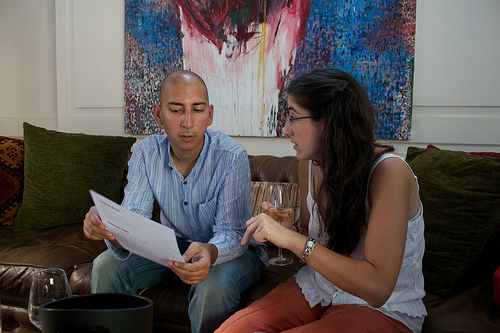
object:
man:
[82, 67, 272, 332]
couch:
[0, 118, 499, 331]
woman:
[214, 68, 434, 333]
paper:
[88, 188, 187, 271]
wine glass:
[266, 183, 295, 267]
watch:
[298, 235, 319, 267]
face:
[306, 240, 315, 249]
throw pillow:
[9, 121, 137, 237]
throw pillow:
[400, 144, 500, 299]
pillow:
[0, 134, 26, 229]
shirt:
[103, 127, 272, 268]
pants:
[213, 272, 415, 332]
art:
[120, 0, 419, 140]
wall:
[1, 0, 500, 160]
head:
[152, 70, 214, 151]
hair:
[283, 66, 397, 257]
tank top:
[294, 151, 432, 333]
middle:
[178, 0, 311, 138]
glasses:
[285, 111, 313, 124]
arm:
[241, 157, 413, 309]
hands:
[165, 240, 213, 286]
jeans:
[91, 234, 265, 333]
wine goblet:
[28, 267, 75, 333]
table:
[1, 329, 173, 333]